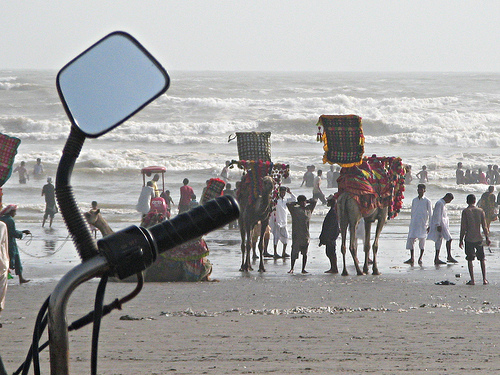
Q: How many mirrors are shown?
A: One.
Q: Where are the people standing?
A: On the beach.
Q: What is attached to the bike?
A: A mirror.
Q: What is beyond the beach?
A: The water.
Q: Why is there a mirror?
A: To see behind the bike.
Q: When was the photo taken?
A: Daytime.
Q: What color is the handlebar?
A: Black.